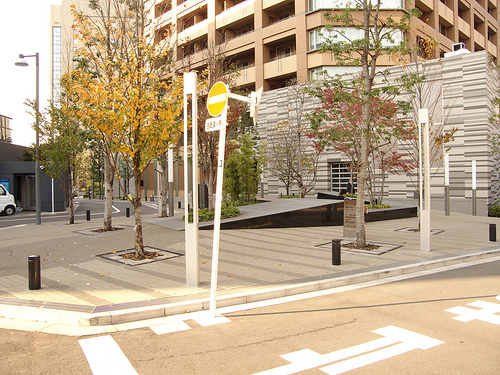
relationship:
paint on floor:
[220, 317, 446, 372] [0, 194, 499, 373]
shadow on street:
[422, 257, 497, 275] [104, 286, 498, 369]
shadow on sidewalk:
[10, 214, 482, 294] [3, 208, 499, 324]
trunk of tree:
[354, 183, 369, 249] [304, 6, 464, 274]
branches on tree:
[426, 75, 443, 123] [397, 47, 448, 223]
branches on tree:
[438, 96, 452, 146] [397, 47, 448, 223]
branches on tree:
[423, 56, 439, 87] [397, 47, 448, 223]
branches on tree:
[400, 139, 419, 154] [397, 47, 448, 223]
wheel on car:
[4, 204, 20, 217] [0, 182, 17, 215]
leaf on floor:
[85, 280, 92, 287] [0, 194, 499, 373]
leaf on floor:
[97, 272, 105, 277] [0, 194, 499, 373]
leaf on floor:
[107, 270, 112, 275] [0, 194, 499, 373]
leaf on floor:
[60, 257, 65, 262] [0, 194, 499, 373]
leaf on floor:
[72, 270, 79, 276] [0, 194, 499, 373]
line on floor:
[145, 308, 229, 333] [0, 252, 492, 371]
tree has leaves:
[59, 0, 212, 259] [108, 80, 121, 95]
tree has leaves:
[59, 0, 212, 259] [143, 69, 163, 91]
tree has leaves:
[59, 0, 212, 259] [68, 81, 83, 106]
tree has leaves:
[59, 0, 212, 259] [107, 116, 125, 128]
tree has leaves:
[59, 0, 212, 259] [157, 123, 170, 142]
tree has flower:
[308, 0, 459, 250] [308, 137, 325, 153]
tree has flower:
[308, 0, 459, 250] [378, 150, 410, 172]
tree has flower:
[308, 0, 459, 250] [323, 86, 336, 101]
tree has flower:
[308, 0, 459, 250] [383, 100, 396, 110]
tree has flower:
[308, 0, 459, 250] [334, 122, 351, 132]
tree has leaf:
[308, 0, 459, 250] [302, 112, 313, 121]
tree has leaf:
[308, 0, 459, 250] [380, 85, 390, 95]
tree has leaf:
[308, 0, 459, 250] [316, 41, 326, 49]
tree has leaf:
[308, 0, 459, 250] [354, 2, 362, 9]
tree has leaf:
[308, 0, 459, 250] [381, 67, 391, 77]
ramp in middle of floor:
[180, 190, 350, 235] [0, 194, 499, 373]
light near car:
[16, 51, 46, 223] [2, 178, 16, 225]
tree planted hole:
[76, 25, 183, 260] [120, 252, 152, 259]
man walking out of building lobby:
[344, 177, 360, 196] [286, 67, 396, 214]